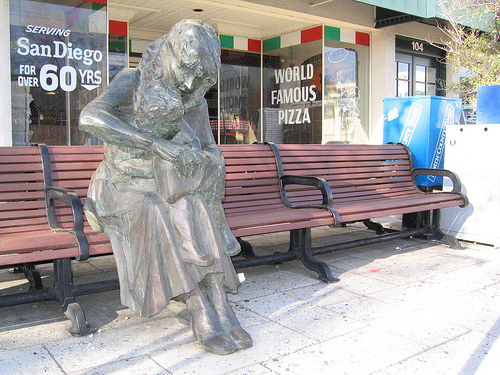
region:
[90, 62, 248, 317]
A woman statute on a bench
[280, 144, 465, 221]
A brown street bench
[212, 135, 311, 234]
A brown street bench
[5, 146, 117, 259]
A brown street bench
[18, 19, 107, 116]
A glass with writings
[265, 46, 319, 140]
A glass with writings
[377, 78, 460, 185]
A blue street bin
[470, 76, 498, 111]
A blue street bin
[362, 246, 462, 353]
A grey surface ground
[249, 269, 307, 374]
A grey surface ground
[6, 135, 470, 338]
A group of benches on the sidewalk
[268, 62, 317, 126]
Letters in a building's window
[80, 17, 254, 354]
Large statue of a seated woman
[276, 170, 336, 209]
Arm rest of a bench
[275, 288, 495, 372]
Footpath made of cement blocks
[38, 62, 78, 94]
Numbers on the front of a window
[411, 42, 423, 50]
Numbers above a building's entrance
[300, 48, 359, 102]
Painting hanging behind a window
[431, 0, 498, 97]
Branches on a small tree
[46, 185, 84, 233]
Arm rest of a bench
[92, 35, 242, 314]
this is a statue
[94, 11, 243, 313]
the statue is sitted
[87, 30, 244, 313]
the statue is silvery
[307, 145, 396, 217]
this is a bench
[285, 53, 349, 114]
this is a window glass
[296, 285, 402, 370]
this is the floor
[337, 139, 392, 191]
the bench is empty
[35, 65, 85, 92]
it is written 60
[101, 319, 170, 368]
the floor is dusty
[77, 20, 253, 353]
A large statue of a woman looking in her purse.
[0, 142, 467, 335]
A row of wooden benches with metal frames.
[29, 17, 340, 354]
The statue is seated on a bench.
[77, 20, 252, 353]
A statue of a woman wearing a dress and flat shoes.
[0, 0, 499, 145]
A building storefront behind the statue.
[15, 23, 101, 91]
White writing on the window describing the age of the business.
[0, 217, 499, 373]
A brick paved ground.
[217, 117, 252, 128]
A red checkered table cloth inside of the business.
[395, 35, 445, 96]
A door with a brown frame and glass windows.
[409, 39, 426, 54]
Address numbers above the door.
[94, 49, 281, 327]
statue sitting on bench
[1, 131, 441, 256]
brown benches on sidewalk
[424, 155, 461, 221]
black armrests on bench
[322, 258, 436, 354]
sidewalk is grey tile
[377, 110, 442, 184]
blue and white newspaper holder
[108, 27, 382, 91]
red white and green sign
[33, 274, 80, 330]
black legs on bench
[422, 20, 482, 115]
green tree behind bench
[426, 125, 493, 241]
white box near bench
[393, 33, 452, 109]
black door behind newspaper dispenser